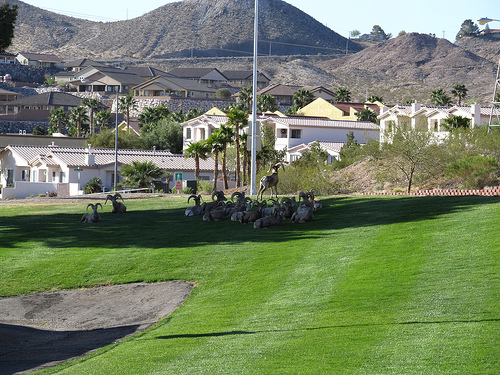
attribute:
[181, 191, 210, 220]
ram sitting — white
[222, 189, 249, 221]
ram sitting — white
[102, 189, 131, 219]
ram sitting — white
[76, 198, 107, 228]
ram sitting — white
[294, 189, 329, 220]
ram sitting — white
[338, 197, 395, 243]
grass — green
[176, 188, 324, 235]
animals — laying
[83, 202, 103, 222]
ram — white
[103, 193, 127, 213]
ram — white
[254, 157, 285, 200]
ram — white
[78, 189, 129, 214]
horns — large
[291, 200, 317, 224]
ram — white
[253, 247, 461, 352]
grass — green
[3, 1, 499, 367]
view — beautiful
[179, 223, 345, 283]
grass field — green 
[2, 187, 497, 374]
field — grass  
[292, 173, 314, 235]
ram — white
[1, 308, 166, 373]
shadow — gray, squarish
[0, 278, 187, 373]
road — dead end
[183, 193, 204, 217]
ram — white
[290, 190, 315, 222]
ram — white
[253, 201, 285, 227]
ram — white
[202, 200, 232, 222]
ram — white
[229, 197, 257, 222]
ram — white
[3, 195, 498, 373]
grass — green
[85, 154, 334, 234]
animals — laying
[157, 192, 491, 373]
line — white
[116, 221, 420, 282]
grass field — green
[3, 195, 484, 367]
field — grass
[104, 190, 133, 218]
ram — white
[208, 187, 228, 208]
ram — white